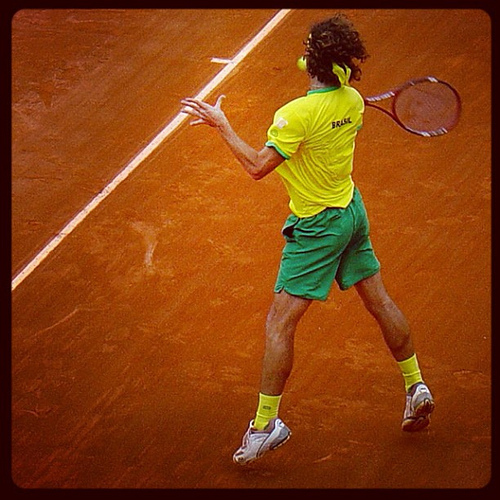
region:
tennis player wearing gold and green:
[179, 18, 464, 458]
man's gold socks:
[232, 353, 435, 463]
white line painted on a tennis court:
[13, 161, 145, 298]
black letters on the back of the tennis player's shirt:
[330, 117, 352, 128]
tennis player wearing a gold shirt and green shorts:
[229, 25, 433, 462]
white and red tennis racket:
[366, 75, 463, 137]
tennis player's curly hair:
[305, 18, 364, 88]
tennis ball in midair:
[295, 55, 308, 75]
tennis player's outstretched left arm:
[180, 90, 282, 180]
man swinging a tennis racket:
[178, 17, 460, 457]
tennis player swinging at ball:
[165, 10, 477, 470]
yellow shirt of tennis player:
[266, 75, 366, 211]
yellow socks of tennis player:
[246, 346, 421, 426]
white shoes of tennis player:
[230, 380, 430, 470]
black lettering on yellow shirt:
[330, 115, 352, 130]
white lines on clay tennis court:
[12, 7, 297, 287]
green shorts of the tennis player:
[266, 211, 384, 294]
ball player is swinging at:
[293, 55, 308, 69]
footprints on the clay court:
[98, 144, 416, 409]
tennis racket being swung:
[364, 68, 464, 141]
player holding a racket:
[157, 29, 457, 433]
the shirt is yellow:
[266, 88, 433, 283]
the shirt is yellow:
[226, 83, 392, 240]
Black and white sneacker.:
[218, 418, 295, 462]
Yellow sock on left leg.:
[255, 382, 279, 443]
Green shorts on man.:
[282, 199, 382, 317]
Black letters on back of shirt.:
[324, 116, 378, 137]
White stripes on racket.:
[411, 123, 455, 141]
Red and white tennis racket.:
[365, 76, 467, 153]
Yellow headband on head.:
[291, 49, 359, 89]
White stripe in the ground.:
[65, 118, 152, 273]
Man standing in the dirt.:
[180, 18, 477, 472]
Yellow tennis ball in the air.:
[291, 43, 313, 73]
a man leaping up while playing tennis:
[180, 16, 455, 465]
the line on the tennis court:
[23, 15, 295, 307]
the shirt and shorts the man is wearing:
[258, 83, 385, 293]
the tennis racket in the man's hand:
[365, 75, 464, 143]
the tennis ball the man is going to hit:
[293, 52, 309, 72]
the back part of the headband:
[332, 64, 357, 91]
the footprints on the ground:
[121, 318, 481, 440]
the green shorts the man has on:
[263, 205, 380, 297]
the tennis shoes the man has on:
[228, 380, 438, 466]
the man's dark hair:
[308, 15, 365, 87]